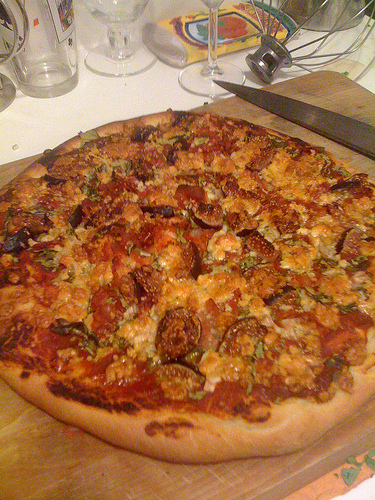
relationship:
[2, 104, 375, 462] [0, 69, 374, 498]
pizza on board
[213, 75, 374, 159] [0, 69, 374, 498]
knife on board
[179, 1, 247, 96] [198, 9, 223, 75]
glass has stem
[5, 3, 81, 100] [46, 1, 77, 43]
glass displays jack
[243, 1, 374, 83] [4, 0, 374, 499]
whisk on counter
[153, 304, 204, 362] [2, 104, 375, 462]
topping on pizza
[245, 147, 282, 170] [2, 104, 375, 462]
topping on pizza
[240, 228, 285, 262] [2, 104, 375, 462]
topping on pizza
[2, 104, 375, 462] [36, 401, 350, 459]
pizza has crust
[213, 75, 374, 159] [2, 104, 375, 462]
knife next to pizza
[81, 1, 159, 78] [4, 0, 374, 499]
glass on counter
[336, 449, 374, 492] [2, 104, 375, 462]
leaf beside pizza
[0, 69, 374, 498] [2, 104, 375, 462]
board under pizza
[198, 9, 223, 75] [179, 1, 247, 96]
stem of glass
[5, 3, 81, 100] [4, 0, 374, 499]
glass on counter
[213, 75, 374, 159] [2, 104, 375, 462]
knife near pizza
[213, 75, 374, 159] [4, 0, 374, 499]
knife on counter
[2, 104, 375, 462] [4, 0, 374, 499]
pizza on counter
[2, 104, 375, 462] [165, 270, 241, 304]
pizza has cheese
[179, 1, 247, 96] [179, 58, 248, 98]
glass has bottom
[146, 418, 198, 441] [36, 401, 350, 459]
spot on crust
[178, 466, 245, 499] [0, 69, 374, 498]
cuts on board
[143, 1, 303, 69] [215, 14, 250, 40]
package has picture